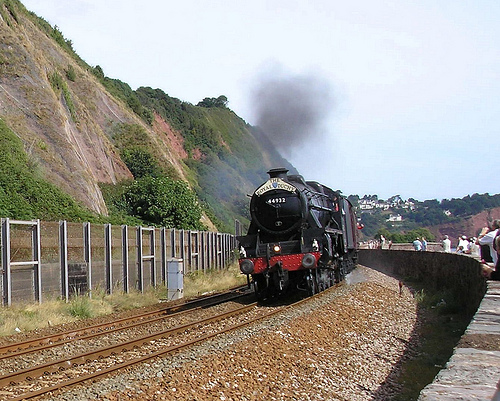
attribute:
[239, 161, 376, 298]
train — black, red, long, large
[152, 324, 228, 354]
tracks — parallel, tan, rusty, rusted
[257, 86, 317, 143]
smoke — black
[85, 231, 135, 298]
fence — large, long, black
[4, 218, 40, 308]
wall — stone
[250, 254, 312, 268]
plate — red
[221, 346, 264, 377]
gravel — tan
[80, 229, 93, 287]
post — white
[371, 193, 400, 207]
buildings — white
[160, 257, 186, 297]
box — gray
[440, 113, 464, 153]
sky — blue